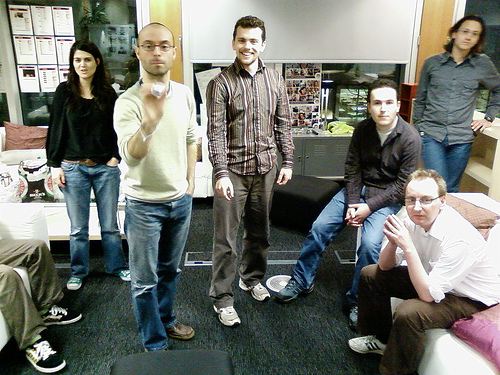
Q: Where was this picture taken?
A: In a room.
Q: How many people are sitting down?
A: Three.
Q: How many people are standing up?
A: Four.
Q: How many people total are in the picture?
A: Seven.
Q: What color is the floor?
A: Grey.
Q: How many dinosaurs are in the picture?
A: Zero.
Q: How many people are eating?
A: Zero.